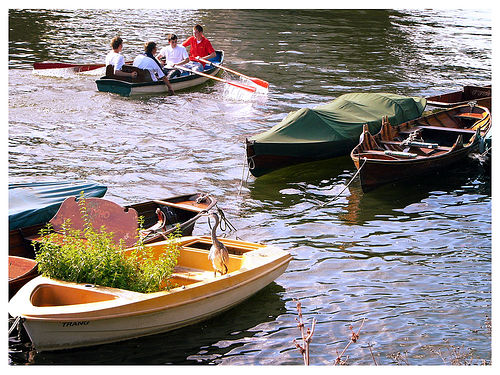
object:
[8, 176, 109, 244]
boat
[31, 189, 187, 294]
foliage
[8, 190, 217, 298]
boat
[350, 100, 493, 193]
boat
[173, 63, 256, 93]
oar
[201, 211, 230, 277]
bird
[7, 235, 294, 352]
boat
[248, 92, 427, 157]
cover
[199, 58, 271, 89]
paddle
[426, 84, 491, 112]
boat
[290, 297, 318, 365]
branch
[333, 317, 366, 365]
branch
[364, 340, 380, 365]
branch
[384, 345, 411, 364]
branch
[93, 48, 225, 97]
boat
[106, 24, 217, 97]
family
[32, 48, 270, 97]
rowboat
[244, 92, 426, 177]
boat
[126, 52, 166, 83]
shirt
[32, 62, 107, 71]
wood oars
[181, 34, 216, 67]
shirt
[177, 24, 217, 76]
boy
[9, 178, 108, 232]
cover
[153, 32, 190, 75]
guy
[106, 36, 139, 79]
guy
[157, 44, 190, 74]
shirt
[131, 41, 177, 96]
guy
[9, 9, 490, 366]
lake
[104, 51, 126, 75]
shirt